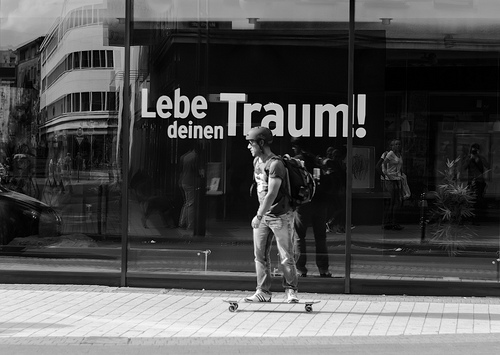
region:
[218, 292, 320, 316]
A white skateboard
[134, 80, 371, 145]
White words on a building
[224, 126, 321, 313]
A man on a skateboard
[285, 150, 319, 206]
A back pack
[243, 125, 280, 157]
A man wearing a helmet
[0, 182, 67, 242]
A car reflected on the side of a building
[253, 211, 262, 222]
A man's wristwatch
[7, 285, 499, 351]
A brick paved sidewalk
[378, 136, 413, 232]
A reflection of a woman across the street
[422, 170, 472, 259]
A plant inside the building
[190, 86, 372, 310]
man on the sidewalk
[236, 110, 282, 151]
helmet on the man's head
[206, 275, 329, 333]
board on the ground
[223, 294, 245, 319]
wheels on the board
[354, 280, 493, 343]
shadow on the ground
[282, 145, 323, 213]
backpack on the man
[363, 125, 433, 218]
reflection of a person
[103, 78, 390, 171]
words on the building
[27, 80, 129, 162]
reflection of a building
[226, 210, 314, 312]
pants on the man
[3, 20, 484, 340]
black and white photo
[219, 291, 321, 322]
board under the man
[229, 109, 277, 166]
helmet on the man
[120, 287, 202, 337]
ground in front of man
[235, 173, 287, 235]
arm of the man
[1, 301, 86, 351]
shadow on the ground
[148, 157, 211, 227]
reflection in the window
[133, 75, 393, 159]
words on the window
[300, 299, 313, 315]
part fo a wheel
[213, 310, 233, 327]
part of a floor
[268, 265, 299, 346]
part of a board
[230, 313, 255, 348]
part of a shade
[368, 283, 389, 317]
edge fo a road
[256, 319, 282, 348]
edge of a hand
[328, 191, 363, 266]
part of a post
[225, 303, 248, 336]
part of a floor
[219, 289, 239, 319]
part of a wheel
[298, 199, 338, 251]
part of a mirror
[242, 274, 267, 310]
part of a shoe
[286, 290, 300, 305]
edge of a shoe